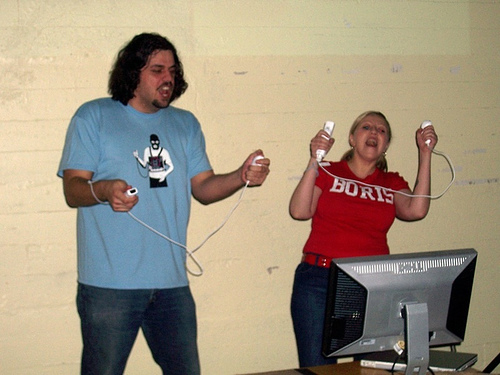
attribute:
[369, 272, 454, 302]
back — silver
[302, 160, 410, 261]
shirt — red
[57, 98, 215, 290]
shirt — blue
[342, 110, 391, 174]
hair — blonde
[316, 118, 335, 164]
wii — white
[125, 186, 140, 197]
controller — white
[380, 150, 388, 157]
earring — hoop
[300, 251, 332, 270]
belt — red, shiny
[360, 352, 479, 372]
laptop — computer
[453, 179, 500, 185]
crack — grey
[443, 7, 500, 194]
wall — tan, brick, cream, painted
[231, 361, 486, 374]
table — brown, wooden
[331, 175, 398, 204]
logo — corporate